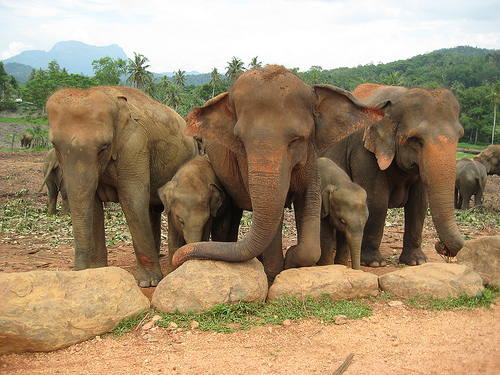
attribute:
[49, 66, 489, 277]
elephants — grouped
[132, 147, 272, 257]
elephant — grouped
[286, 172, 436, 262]
elephant — grouped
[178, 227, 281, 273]
trunk — resting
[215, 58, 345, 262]
elephant — large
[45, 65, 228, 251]
elephant — large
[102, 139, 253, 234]
elephant — small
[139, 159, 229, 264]
elephant — small, grey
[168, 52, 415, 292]
elephant — large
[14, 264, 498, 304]
rocks — lined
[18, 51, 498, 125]
trees — green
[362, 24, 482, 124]
hill — green, large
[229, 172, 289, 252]
trunk — long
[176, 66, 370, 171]
ears — big, floppy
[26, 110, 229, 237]
elephant — grey, brown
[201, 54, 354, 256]
elephant — gray, brown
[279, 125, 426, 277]
elephant — brown, grey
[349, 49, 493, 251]
elephant — grey, brown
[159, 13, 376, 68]
clouds — white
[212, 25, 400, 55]
clouds — white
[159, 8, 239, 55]
clouds — white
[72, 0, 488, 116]
sky — blue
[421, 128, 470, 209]
spot — orange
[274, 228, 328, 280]
hoof — bent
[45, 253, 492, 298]
rocks — tan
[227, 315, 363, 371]
soil — rocky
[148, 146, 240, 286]
elephant — small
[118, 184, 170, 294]
leg — long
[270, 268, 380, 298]
rock — large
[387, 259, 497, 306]
rock — large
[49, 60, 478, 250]
elephants — group 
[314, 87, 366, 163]
ear — middle elephants left 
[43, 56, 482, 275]
elephant — eyes 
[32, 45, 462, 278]
elephant — baby 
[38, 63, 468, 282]
elephant — baby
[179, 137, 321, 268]
trunk — center elephant's 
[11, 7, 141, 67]
mountain — distance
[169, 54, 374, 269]
elephant — baby 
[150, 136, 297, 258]
trunk — elephants  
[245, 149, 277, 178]
spot — orange  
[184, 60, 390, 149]
ears — sticking out 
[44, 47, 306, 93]
trees — line 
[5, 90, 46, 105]
building — white , distance 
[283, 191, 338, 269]
leg — raised 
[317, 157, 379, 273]
elephant —  small baby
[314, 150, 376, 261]
elephant —  small baby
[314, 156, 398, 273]
elephant —  small baby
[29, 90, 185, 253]
elephant — large adult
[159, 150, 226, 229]
elephant — baby